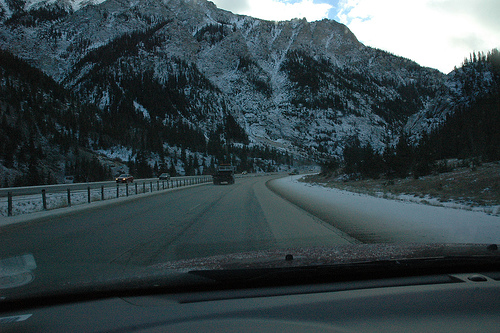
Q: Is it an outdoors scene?
A: Yes, it is outdoors.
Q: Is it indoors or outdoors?
A: It is outdoors.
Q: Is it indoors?
A: No, it is outdoors.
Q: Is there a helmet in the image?
A: No, there are no helmets.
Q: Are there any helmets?
A: No, there are no helmets.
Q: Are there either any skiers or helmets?
A: No, there are no helmets or skiers.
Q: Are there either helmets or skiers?
A: No, there are no helmets or skiers.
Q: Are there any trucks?
A: Yes, there is a truck.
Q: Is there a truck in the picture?
A: Yes, there is a truck.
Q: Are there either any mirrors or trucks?
A: Yes, there is a truck.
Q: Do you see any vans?
A: No, there are no vans.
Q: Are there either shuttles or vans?
A: No, there are no vans or shuttles.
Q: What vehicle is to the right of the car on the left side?
A: The vehicle is a truck.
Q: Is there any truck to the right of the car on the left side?
A: Yes, there is a truck to the right of the car.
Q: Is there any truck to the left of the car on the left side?
A: No, the truck is to the right of the car.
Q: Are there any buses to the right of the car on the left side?
A: No, there is a truck to the right of the car.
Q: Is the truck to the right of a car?
A: Yes, the truck is to the right of a car.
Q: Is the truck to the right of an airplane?
A: No, the truck is to the right of a car.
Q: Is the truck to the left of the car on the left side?
A: No, the truck is to the right of the car.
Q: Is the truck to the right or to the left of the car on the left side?
A: The truck is to the right of the car.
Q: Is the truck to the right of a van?
A: No, the truck is to the right of a car.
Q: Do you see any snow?
A: Yes, there is snow.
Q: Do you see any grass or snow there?
A: Yes, there is snow.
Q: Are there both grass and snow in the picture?
A: No, there is snow but no grass.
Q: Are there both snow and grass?
A: No, there is snow but no grass.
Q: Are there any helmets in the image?
A: No, there are no helmets.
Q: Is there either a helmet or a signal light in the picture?
A: No, there are no helmets or traffic lights.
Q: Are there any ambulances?
A: No, there are no ambulances.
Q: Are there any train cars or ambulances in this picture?
A: No, there are no ambulances or train cars.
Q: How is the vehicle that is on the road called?
A: The vehicle is a car.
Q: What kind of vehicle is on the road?
A: The vehicle is a car.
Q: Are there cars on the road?
A: Yes, there is a car on the road.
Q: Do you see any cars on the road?
A: Yes, there is a car on the road.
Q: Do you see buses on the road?
A: No, there is a car on the road.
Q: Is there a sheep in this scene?
A: No, there is no sheep.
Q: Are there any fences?
A: Yes, there is a fence.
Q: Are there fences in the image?
A: Yes, there is a fence.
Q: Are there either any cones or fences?
A: Yes, there is a fence.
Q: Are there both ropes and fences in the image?
A: No, there is a fence but no ropes.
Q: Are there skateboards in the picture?
A: No, there are no skateboards.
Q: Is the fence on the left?
A: Yes, the fence is on the left of the image.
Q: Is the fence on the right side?
A: No, the fence is on the left of the image.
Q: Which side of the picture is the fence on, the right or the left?
A: The fence is on the left of the image.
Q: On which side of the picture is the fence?
A: The fence is on the left of the image.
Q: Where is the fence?
A: The fence is on the road.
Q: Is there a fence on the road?
A: Yes, there is a fence on the road.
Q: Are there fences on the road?
A: Yes, there is a fence on the road.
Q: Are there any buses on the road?
A: No, there is a fence on the road.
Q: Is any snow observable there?
A: Yes, there is snow.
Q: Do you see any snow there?
A: Yes, there is snow.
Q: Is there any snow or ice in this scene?
A: Yes, there is snow.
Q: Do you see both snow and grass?
A: No, there is snow but no grass.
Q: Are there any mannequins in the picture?
A: No, there are no mannequins.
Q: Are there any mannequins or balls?
A: No, there are no mannequins or balls.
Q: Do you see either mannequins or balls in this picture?
A: No, there are no mannequins or balls.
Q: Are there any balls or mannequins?
A: No, there are no mannequins or balls.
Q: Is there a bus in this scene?
A: No, there are no buses.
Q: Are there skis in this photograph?
A: No, there are no skis.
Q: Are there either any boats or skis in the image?
A: No, there are no skis or boats.